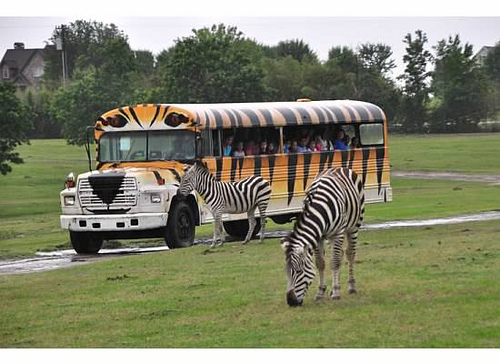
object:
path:
[1, 206, 500, 283]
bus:
[57, 97, 397, 253]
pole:
[60, 32, 73, 95]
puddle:
[50, 240, 161, 260]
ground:
[393, 157, 444, 183]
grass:
[0, 251, 500, 349]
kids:
[214, 134, 236, 155]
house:
[0, 40, 87, 131]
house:
[461, 42, 500, 97]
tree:
[392, 25, 440, 132]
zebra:
[178, 161, 272, 248]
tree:
[422, 35, 500, 133]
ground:
[401, 208, 495, 249]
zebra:
[279, 164, 366, 308]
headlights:
[63, 195, 75, 206]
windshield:
[95, 128, 200, 165]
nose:
[80, 165, 133, 209]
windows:
[202, 126, 280, 158]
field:
[0, 241, 500, 348]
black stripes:
[375, 145, 387, 196]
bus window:
[283, 121, 385, 155]